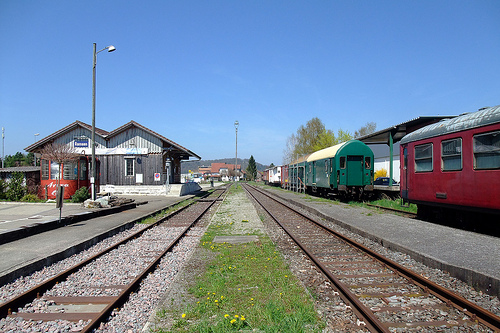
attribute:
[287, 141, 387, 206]
train car — green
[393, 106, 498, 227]
train car — red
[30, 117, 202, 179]
building — gray, small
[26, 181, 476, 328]
tracks — brown, empty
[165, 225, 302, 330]
plants — green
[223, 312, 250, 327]
flowers — yellow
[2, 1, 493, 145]
sky — blue, clear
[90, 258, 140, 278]
gravel — gray